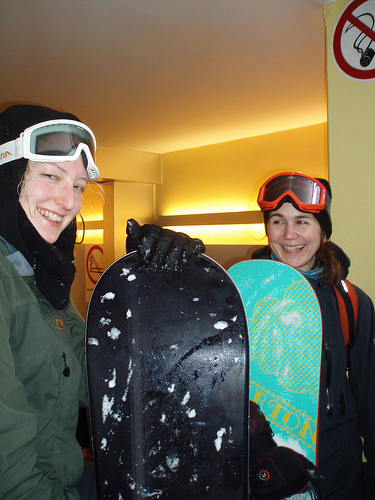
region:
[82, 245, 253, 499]
black snow board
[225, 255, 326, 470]
green and yellow snowboard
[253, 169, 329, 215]
orange snow goggles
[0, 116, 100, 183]
white snow goggles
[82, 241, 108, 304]
red and white no smoking sign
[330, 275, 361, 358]
red and black backpack shoulder strap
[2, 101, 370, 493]
two women standing together with two snowboards between them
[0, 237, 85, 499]
green jacket with black zipper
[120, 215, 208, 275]
black snow gloves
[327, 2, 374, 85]
red and white no smoking sign on wall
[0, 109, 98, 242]
a woman smiling at the camera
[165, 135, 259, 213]
a wall with a lightsource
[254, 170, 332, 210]
skiing googles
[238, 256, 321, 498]
a light blue snowboard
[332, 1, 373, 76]
a no smoking sign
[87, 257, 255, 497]
a snowboard with snow on it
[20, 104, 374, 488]
two woman holding snowboards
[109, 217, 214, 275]
a hand and a glove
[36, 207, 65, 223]
a row of teeth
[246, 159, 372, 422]
a lady in a skiing suit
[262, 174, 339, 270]
the head of the woman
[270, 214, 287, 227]
the eye of the woman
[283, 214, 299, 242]
the nose of the woman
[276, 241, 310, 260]
the mouth of the woman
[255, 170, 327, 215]
a pair of red goggles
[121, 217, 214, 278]
a black glove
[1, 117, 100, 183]
a pair of white goggles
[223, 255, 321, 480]
an aqua snowboard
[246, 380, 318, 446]
yellow writing on the snowboard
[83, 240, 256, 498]
a black snowboard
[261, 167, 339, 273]
the head of a woman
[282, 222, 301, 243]
the nose of a woman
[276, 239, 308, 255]
the mouth of a woman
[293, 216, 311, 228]
the eye of a woman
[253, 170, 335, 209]
a pair of orange goggles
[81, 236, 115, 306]
a red and white sign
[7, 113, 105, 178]
White goggles on a woman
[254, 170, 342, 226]
Orange goggles on a woman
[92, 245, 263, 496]
Bottom of a snowboard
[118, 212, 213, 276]
Black glove on a woman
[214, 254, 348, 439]
Green and yellow snowboard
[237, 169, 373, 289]
Woman with brown hair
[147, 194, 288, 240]
Lights on a wall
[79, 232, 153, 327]
No smoking sign in a room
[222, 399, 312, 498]
Purple glove on a hand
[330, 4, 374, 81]
Red and white no smoking sign